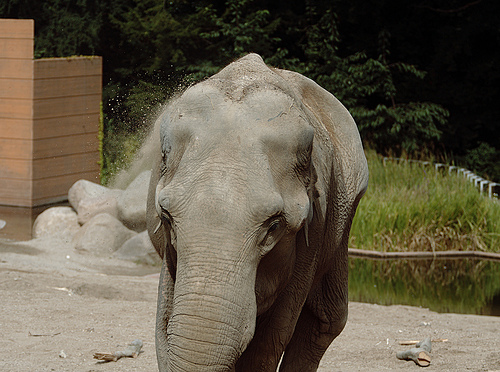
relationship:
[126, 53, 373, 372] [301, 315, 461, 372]
elephant in dirt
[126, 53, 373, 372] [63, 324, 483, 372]
elephant in dirt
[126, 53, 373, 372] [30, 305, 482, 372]
elephant in dirt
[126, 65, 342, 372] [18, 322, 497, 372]
elephant in dirt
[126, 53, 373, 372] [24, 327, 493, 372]
elephant in dirt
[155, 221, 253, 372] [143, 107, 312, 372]
trunk on elephant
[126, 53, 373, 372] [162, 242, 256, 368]
elephant has a trunk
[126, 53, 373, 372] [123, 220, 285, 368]
elephant has a trunk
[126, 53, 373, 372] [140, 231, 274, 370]
elephant has a trunk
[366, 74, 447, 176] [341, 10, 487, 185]
leaves on tree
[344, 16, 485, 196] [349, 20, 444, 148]
leaves on tree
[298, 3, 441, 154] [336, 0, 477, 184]
leaves on tree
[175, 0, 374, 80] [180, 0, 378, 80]
leaves on tree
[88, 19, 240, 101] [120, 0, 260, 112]
leaves on tree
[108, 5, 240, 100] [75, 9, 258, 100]
leaves on tree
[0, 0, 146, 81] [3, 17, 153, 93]
leaves on tree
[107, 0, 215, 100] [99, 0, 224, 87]
leaves on tree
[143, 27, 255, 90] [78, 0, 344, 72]
leaves on tree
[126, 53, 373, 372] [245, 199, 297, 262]
elephant has an eye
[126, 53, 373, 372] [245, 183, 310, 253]
elephant has an eye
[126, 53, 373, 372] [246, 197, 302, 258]
elephant has an eye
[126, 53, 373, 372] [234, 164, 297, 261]
elephant has an eye